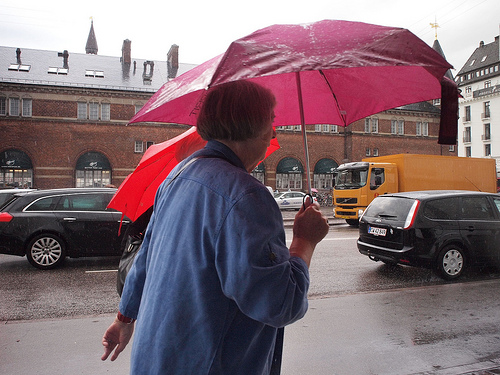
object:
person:
[103, 78, 330, 374]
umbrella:
[123, 20, 465, 127]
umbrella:
[104, 123, 281, 235]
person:
[115, 204, 155, 297]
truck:
[330, 153, 498, 227]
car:
[271, 188, 319, 210]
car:
[0, 187, 144, 271]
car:
[357, 190, 499, 282]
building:
[454, 34, 499, 186]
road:
[1, 222, 497, 324]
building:
[1, 44, 457, 196]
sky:
[1, 1, 499, 74]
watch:
[115, 310, 135, 326]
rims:
[29, 235, 62, 266]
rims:
[442, 249, 465, 275]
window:
[465, 104, 471, 121]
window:
[482, 101, 490, 118]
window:
[482, 121, 490, 140]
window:
[463, 126, 473, 142]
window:
[465, 144, 472, 157]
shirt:
[116, 138, 310, 374]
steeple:
[84, 19, 99, 55]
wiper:
[377, 212, 396, 220]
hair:
[196, 79, 276, 141]